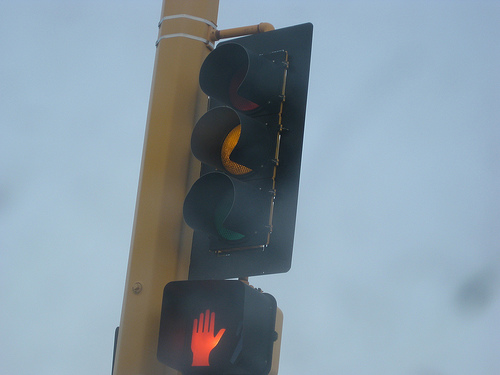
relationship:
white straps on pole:
[156, 12, 217, 48] [111, 1, 221, 373]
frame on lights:
[179, 18, 316, 280] [220, 121, 247, 172]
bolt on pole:
[123, 266, 151, 306] [86, 1, 336, 374]